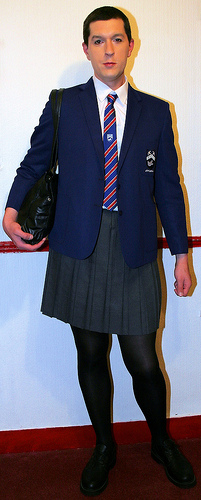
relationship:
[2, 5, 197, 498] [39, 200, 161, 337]
man wearing skirt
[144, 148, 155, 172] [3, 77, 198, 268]
emblem on jacket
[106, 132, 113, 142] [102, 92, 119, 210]
emblem on tie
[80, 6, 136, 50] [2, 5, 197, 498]
hair on man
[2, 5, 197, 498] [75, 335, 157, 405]
man wearing tights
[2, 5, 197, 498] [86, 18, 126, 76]
man wearing makeup